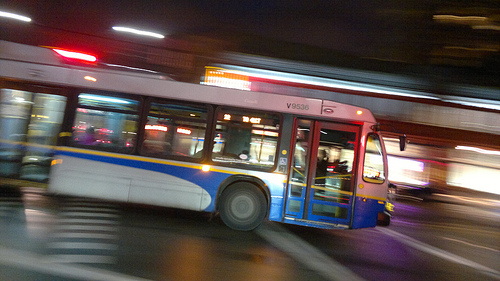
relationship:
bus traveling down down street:
[0, 39, 407, 232] [0, 181, 500, 281]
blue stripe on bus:
[44, 146, 295, 232] [0, 39, 407, 232]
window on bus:
[360, 131, 386, 183] [0, 39, 407, 232]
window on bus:
[209, 103, 284, 170] [0, 39, 407, 232]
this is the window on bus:
[138, 98, 209, 160] [0, 39, 407, 232]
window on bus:
[70, 90, 142, 152] [0, 39, 407, 232]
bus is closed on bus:
[281, 114, 364, 227] [0, 39, 407, 232]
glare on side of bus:
[1, 74, 387, 219] [0, 39, 407, 232]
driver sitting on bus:
[317, 150, 348, 177] [0, 39, 407, 232]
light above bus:
[48, 46, 98, 66] [0, 39, 407, 232]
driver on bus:
[317, 149, 341, 193] [0, 39, 407, 232]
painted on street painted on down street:
[134, 217, 458, 279] [0, 181, 500, 281]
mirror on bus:
[396, 132, 407, 150] [0, 39, 407, 232]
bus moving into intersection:
[0, 39, 407, 232] [1, 0, 498, 278]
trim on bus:
[0, 140, 387, 230] [0, 39, 407, 232]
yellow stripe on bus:
[65, 145, 401, 252] [0, 39, 407, 232]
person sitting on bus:
[83, 125, 101, 147] [0, 39, 407, 232]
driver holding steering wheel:
[317, 149, 341, 193] [324, 153, 369, 189]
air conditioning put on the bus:
[4, 36, 70, 75] [165, 63, 325, 146]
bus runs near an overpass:
[0, 39, 407, 232] [101, 0, 497, 70]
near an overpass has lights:
[0, 0, 498, 211] [2, 9, 279, 82]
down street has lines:
[0, 181, 500, 281] [254, 218, 369, 281]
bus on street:
[0, 39, 407, 232] [1, 204, 497, 279]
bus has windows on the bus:
[2, 50, 408, 241] [65, 90, 352, 191]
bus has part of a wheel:
[2, 50, 408, 241] [217, 181, 269, 231]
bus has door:
[2, 50, 408, 241] [279, 116, 364, 234]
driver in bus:
[317, 150, 348, 177] [2, 50, 408, 241]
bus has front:
[2, 50, 408, 241] [347, 97, 401, 233]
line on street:
[375, 220, 498, 277] [90, 213, 413, 280]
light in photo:
[48, 48, 97, 63] [68, 54, 359, 279]